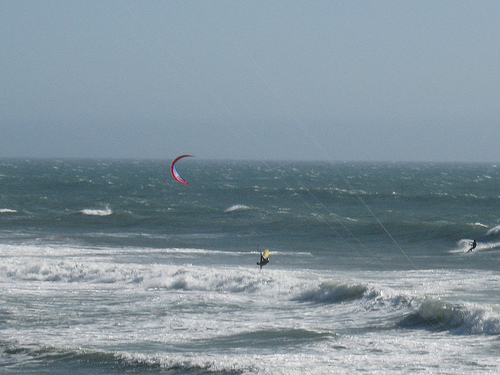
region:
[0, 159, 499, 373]
water below sky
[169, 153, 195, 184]
kite flying above the water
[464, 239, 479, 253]
person is in the water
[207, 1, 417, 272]
white cable extending from the water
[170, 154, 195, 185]
the kite is "c" shaped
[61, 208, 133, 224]
wave in the water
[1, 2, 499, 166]
the sky is a hazy gray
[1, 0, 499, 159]
sky above person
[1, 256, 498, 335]
a big white wave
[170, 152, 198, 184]
the kite is red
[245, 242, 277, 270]
a person flying a kite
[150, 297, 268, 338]
the ocean water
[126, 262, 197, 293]
the water is white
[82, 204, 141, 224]
a small wave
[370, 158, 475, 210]
the ocean is blue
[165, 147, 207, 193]
a kite in the sky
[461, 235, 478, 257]
a person surfing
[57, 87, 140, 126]
the sky is clear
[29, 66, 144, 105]
a clear sky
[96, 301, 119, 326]
waves in the water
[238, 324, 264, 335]
waves in the water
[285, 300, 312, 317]
waves in the water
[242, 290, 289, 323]
waves in the water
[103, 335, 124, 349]
waves in the water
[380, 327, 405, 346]
waves in the water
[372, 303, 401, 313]
waves in the water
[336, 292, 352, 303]
waves in the water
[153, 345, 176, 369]
waves in the water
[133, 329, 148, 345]
waves in the water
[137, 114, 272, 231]
Kite in the air.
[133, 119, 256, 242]
Kite in the sky.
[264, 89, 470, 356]
Strings on the kite.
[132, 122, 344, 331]
Person with a kite.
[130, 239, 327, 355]
White caps on the waves.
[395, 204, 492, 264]
Person in the water skiing.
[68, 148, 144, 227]
Waves in the distance.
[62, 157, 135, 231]
White caps on the waves.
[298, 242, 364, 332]
Large wave.